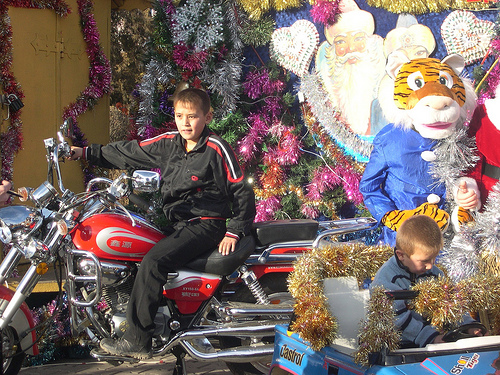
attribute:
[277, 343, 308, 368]
sign — castrol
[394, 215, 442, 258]
hair — blonde, boy's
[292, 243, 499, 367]
tinsel — gold colored, christmas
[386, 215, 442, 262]
hair — blonde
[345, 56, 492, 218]
mascot — tiger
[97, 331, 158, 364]
sneakers — black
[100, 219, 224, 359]
pants — black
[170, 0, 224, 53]
snowflake — large, decorative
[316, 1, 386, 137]
santa — picture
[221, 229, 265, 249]
cuff — red, white, striped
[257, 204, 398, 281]
car — kid's, blue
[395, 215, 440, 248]
hair — short, brown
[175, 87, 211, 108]
hair — short, brown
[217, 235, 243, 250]
left hand — boy's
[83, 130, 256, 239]
jacket — red, black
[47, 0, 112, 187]
tinsel — pink and green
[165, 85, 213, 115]
hair — brown